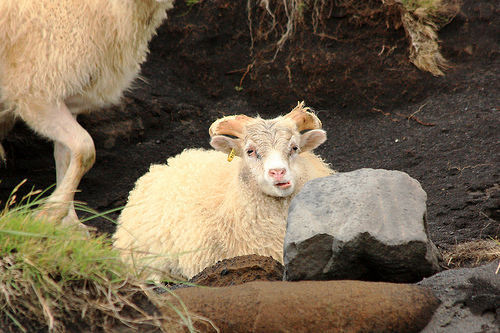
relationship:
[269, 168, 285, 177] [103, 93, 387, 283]
nose of goat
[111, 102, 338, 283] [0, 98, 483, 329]
goat on ground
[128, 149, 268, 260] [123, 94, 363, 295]
body of sheep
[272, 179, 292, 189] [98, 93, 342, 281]
mouth of sheep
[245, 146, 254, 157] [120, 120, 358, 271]
eye of sheep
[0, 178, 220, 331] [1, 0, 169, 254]
grass under goat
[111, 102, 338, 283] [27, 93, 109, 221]
goat lifting leg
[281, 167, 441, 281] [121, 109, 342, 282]
rock in front of sheep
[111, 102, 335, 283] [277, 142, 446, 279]
goat lying rock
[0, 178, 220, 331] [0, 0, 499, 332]
grass growing in dirt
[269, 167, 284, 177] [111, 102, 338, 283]
nose on goat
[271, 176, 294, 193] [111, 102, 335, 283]
mouth on goat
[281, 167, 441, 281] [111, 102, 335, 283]
rock next to goat